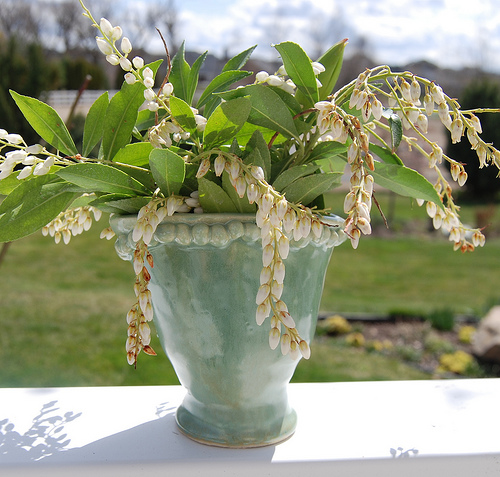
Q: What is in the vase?
A: Flowers.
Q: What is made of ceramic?
A: Vase.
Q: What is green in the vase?
A: Leaves.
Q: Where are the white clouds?
A: Sky.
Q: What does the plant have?
A: White flowers.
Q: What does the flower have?
A: Leaves.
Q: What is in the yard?
A: The green grass.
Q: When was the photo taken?
A: During the daytime.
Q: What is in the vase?
A: Flowers.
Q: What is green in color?
A: The leaves.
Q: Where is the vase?
A: On a white surface.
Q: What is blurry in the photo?
A: Everything behind the vase.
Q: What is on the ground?
A: Grass.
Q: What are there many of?
A: Leaves.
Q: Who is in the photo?
A: No people.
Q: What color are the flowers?
A: White.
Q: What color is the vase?
A: Green.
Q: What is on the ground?
A: Grass.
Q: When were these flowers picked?
A: Fresh.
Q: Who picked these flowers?
A: Someone who likes flowers.